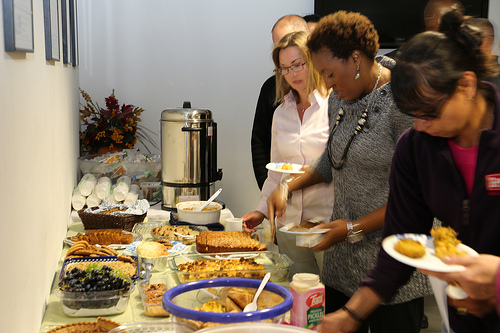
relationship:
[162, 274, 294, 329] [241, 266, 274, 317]
bowl has spoon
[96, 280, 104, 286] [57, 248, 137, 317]
berries on a bowl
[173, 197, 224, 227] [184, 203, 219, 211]
dish has casserole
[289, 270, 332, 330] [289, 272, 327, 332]
bottle of bottle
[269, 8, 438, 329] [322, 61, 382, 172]
woman wears a necklace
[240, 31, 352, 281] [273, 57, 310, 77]
woman wears glasses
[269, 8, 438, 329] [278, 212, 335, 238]
woman has a plate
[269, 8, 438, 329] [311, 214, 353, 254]
woman has a hand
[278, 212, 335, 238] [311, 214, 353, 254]
plate in hand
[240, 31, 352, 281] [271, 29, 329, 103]
woman has hair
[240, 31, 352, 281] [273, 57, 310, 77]
woman has glasses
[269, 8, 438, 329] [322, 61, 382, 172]
woman wearing necklace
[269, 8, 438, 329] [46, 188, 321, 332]
woman getting food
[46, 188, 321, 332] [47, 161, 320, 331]
food on table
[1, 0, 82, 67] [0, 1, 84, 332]
pictures on a wall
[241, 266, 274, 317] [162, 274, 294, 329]
spoon in a bowl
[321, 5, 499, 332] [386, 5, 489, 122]
woman with hair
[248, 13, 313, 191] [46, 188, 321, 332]
man waiting for food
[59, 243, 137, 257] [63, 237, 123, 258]
plate of cookies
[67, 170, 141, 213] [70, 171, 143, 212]
stack of cups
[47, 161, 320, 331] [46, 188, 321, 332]
table has food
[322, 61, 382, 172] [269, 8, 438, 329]
necklace on woman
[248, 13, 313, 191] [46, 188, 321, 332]
man waits for food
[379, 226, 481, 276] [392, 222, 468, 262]
plate has food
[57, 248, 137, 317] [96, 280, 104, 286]
bowl of berries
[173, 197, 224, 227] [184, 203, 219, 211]
dish has a casserole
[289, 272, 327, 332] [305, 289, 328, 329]
bottle has a label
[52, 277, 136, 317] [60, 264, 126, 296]
bowl of berries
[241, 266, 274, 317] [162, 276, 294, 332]
spoon in bowl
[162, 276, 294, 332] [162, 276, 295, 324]
bowl has rim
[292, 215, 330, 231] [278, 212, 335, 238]
food on plate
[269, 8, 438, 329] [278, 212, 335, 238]
woman has plate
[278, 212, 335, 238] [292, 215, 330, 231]
plate of food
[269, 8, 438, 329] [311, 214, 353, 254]
woman has hand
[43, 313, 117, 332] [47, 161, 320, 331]
pie on table